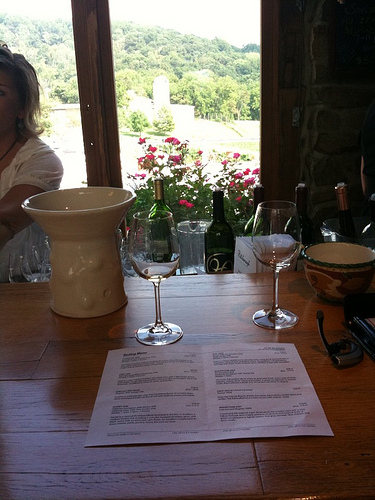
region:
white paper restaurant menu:
[86, 342, 336, 447]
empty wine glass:
[129, 210, 183, 345]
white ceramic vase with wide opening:
[20, 186, 139, 317]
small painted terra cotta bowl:
[301, 239, 374, 302]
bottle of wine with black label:
[203, 188, 235, 272]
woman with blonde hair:
[0, 37, 63, 282]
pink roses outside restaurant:
[122, 134, 260, 215]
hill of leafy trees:
[37, 17, 259, 119]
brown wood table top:
[1, 274, 372, 499]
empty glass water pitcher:
[175, 219, 211, 274]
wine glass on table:
[127, 210, 190, 351]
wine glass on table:
[229, 201, 302, 334]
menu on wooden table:
[98, 341, 331, 454]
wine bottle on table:
[208, 185, 239, 266]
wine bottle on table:
[146, 176, 181, 259]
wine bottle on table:
[290, 183, 324, 249]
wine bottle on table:
[328, 174, 353, 241]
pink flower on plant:
[158, 133, 182, 148]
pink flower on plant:
[241, 177, 252, 187]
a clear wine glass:
[252, 195, 308, 347]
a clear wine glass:
[127, 192, 196, 359]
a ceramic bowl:
[304, 243, 364, 311]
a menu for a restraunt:
[75, 320, 308, 455]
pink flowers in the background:
[112, 144, 262, 203]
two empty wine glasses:
[90, 175, 305, 352]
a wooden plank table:
[29, 316, 273, 486]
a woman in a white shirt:
[0, 90, 83, 231]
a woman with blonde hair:
[2, 88, 86, 146]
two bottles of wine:
[143, 179, 265, 286]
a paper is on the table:
[85, 338, 333, 448]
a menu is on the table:
[86, 340, 339, 457]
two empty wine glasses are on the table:
[122, 199, 302, 347]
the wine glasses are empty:
[124, 196, 301, 346]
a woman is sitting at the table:
[0, 41, 62, 278]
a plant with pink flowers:
[131, 132, 263, 226]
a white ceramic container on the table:
[20, 182, 139, 321]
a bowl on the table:
[301, 235, 373, 301]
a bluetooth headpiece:
[311, 306, 367, 369]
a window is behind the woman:
[0, 0, 281, 223]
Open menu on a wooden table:
[82, 336, 340, 434]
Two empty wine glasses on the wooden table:
[123, 176, 292, 294]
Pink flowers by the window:
[135, 133, 255, 216]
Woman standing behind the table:
[0, 75, 52, 292]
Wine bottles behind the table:
[210, 185, 360, 241]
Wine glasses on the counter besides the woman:
[15, 210, 117, 268]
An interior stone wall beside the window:
[298, 18, 373, 201]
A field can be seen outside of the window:
[28, 3, 250, 123]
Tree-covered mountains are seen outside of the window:
[37, 0, 248, 98]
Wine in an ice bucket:
[320, 192, 371, 242]